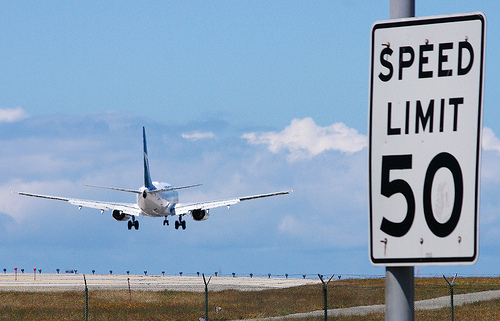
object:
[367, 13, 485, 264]
sign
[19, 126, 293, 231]
plane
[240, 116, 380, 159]
cloud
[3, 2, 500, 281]
sky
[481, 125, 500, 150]
cloud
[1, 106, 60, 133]
cloud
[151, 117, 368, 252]
clouds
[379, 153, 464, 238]
number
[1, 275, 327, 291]
runway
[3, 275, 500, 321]
grass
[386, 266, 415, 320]
pole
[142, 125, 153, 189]
tail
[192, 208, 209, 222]
engine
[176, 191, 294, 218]
wing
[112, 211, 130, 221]
engine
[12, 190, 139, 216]
wing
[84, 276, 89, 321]
post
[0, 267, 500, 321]
fence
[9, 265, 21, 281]
marker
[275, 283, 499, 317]
path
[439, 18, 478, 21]
black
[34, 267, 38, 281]
light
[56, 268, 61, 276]
light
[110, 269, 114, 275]
light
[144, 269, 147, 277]
light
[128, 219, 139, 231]
wheels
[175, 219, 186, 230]
wheels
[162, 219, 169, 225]
wheels